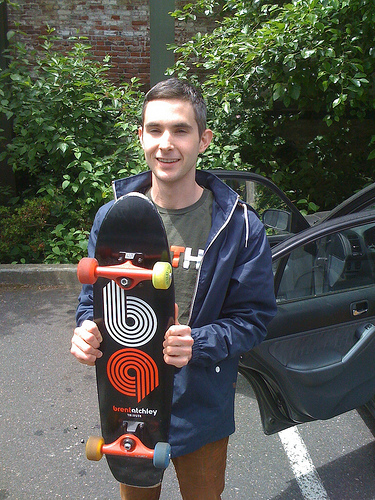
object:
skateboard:
[74, 187, 178, 492]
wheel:
[77, 257, 100, 285]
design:
[102, 278, 160, 419]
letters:
[170, 244, 186, 268]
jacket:
[72, 170, 280, 463]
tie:
[235, 202, 250, 250]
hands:
[161, 302, 194, 369]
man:
[68, 70, 283, 500]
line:
[277, 423, 331, 500]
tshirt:
[140, 184, 216, 327]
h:
[182, 246, 204, 269]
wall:
[0, 0, 229, 100]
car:
[109, 165, 375, 442]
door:
[229, 210, 375, 438]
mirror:
[261, 207, 291, 233]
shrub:
[164, 0, 375, 215]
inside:
[345, 222, 375, 270]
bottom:
[96, 350, 175, 422]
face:
[142, 95, 201, 184]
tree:
[0, 19, 135, 182]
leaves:
[59, 112, 71, 124]